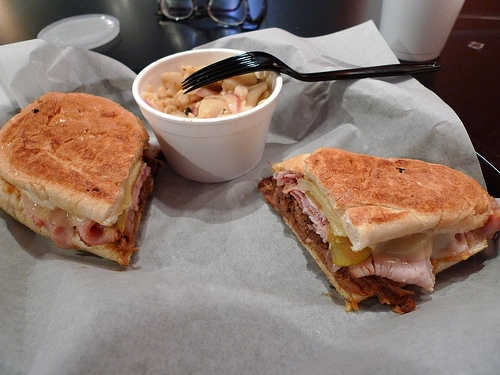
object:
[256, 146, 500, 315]
panini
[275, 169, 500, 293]
ham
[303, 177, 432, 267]
cheese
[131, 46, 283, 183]
cup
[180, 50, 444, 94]
fork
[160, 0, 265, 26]
eyeglasses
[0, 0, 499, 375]
table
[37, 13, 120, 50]
lid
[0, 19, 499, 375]
paper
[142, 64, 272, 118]
pasta salad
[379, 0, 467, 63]
cup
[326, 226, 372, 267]
vegetable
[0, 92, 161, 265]
panini